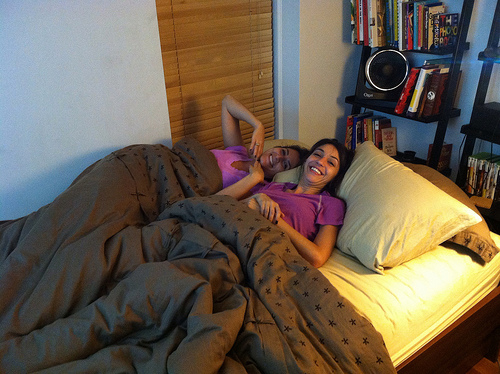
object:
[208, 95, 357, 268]
they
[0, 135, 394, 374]
blanket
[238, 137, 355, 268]
lady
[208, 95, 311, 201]
lady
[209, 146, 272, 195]
shirt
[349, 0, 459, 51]
books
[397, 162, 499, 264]
pillow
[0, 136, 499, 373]
bed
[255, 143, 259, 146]
ring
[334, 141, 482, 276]
pillow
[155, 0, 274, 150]
blind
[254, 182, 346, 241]
shirt